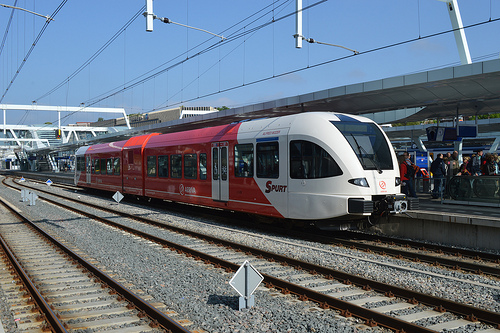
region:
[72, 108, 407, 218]
a red and white train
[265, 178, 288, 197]
red writing on a train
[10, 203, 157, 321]
rusty rail road tracks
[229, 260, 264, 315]
a silver diamond sign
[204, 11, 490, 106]
metal cable wires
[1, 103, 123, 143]
a over pass over a train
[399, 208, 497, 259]
a gray concrete wall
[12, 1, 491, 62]
a crystal clear blue sky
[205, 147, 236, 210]
white double doors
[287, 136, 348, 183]
a side window on a train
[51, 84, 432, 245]
Train parked on the tracks.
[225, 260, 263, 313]
Sign in between tracks.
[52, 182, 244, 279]
Metal tracks in the middle.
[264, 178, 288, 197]
The word spurt on the train.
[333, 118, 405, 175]
Window in the front of the train.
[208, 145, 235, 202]
Door on the side of the train.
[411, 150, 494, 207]
People waiting on the train.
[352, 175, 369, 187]
Light on the front of train.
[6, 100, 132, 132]
Metal railing over tracks.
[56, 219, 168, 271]
Gravel in between the tracks.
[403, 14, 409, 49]
There is a blue sky that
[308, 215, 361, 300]
There is a railroad track that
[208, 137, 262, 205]
There is a white and red train that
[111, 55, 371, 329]
This photo was taken by James Mingus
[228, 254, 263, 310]
There is a sign that is a silver sign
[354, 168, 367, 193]
There is a light on front of the train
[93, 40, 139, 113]
There are wires above the train here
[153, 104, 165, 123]
There is off-white concrete that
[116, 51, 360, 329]
This photo was taken in the city of Dayton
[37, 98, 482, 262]
red and white short train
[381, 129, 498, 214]
people at the platform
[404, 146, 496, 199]
people at the platform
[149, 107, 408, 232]
a red and white train engine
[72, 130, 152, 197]
a red and white train passenger car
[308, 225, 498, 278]
a set of train tracks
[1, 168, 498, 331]
a set of train tracks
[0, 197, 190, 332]
a set of train tracks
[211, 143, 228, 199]
a set of white train doors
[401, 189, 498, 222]
a train boarding platform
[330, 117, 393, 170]
a train front windshield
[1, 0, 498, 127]
a clear blue sky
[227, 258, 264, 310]
a train informational sign